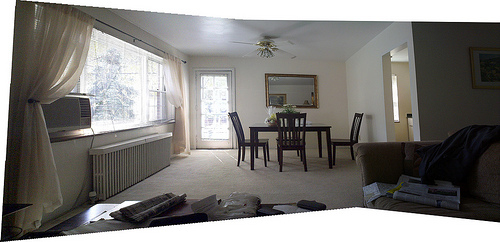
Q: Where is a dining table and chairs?
A: Middle of dining room.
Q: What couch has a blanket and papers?
A: Couch on right.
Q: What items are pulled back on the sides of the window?
A: Curtains.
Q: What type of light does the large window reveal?
A: Daylight.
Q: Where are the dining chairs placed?
A: At table.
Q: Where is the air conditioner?
A: In window.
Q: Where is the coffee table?
A: In foreground.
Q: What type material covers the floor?
A: Carpet.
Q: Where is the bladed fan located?
A: On ceiling.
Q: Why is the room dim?
A: No lights are on.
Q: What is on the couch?
A: A newspaper.